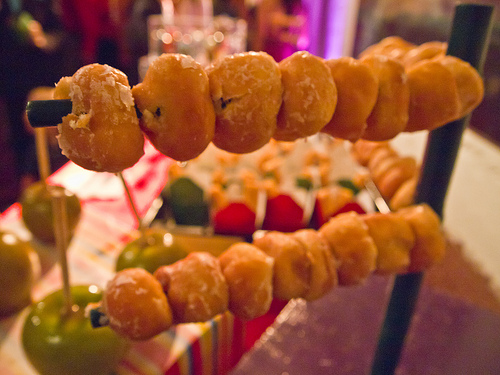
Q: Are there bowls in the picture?
A: No, there are no bowls.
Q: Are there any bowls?
A: No, there are no bowls.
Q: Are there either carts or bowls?
A: No, there are no bowls or carts.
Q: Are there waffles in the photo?
A: No, there are no waffles.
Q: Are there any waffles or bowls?
A: No, there are no waffles or bowls.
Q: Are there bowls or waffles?
A: No, there are no waffles or bowls.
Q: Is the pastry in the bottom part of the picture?
A: Yes, the pastry is in the bottom of the image.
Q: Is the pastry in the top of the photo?
A: No, the pastry is in the bottom of the image.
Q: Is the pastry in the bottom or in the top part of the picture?
A: The pastry is in the bottom of the image.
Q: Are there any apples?
A: Yes, there is an apple.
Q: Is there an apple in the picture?
A: Yes, there is an apple.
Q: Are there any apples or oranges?
A: Yes, there is an apple.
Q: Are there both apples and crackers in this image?
A: No, there is an apple but no crackers.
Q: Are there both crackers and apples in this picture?
A: No, there is an apple but no crackers.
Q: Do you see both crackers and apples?
A: No, there is an apple but no crackers.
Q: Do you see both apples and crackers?
A: No, there is an apple but no crackers.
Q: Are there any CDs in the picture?
A: No, there are no cds.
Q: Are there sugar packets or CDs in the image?
A: No, there are no CDs or sugar packets.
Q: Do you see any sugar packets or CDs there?
A: No, there are no CDs or sugar packets.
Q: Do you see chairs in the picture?
A: No, there are no chairs.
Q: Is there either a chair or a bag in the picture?
A: No, there are no chairs or bags.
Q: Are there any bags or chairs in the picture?
A: No, there are no chairs or bags.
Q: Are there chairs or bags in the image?
A: No, there are no chairs or bags.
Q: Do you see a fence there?
A: No, there are no fences.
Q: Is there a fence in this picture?
A: No, there are no fences.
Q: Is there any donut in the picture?
A: Yes, there is a donut.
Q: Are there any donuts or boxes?
A: Yes, there is a donut.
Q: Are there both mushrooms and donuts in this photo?
A: No, there is a donut but no mushrooms.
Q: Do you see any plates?
A: No, there are no plates.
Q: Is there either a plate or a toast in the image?
A: No, there are no plates or toasts.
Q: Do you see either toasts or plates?
A: No, there are no plates or toasts.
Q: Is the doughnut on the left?
A: Yes, the doughnut is on the left of the image.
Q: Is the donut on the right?
A: No, the donut is on the left of the image.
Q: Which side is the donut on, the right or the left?
A: The donut is on the left of the image.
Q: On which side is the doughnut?
A: The doughnut is on the left of the image.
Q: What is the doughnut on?
A: The doughnut is on the pole.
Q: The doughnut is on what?
A: The doughnut is on the pole.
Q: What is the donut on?
A: The doughnut is on the pole.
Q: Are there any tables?
A: Yes, there is a table.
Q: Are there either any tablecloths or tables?
A: Yes, there is a table.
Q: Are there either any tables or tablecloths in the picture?
A: Yes, there is a table.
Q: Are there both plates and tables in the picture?
A: No, there is a table but no plates.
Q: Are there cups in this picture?
A: No, there are no cups.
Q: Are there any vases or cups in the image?
A: No, there are no cups or vases.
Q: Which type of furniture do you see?
A: The furniture is a table.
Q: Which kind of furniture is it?
A: The piece of furniture is a table.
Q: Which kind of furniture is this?
A: This is a table.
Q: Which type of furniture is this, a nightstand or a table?
A: This is a table.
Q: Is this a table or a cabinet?
A: This is a table.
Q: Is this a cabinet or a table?
A: This is a table.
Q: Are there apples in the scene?
A: Yes, there is an apple.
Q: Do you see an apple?
A: Yes, there is an apple.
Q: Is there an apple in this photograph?
A: Yes, there is an apple.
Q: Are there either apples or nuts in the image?
A: Yes, there is an apple.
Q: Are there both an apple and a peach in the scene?
A: No, there is an apple but no peaches.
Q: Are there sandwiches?
A: No, there are no sandwiches.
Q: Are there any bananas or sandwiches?
A: No, there are no sandwiches or bananas.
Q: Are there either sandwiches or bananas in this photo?
A: No, there are no sandwiches or bananas.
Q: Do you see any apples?
A: Yes, there is an apple.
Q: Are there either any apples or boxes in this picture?
A: Yes, there is an apple.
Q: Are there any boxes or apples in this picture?
A: Yes, there is an apple.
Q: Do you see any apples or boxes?
A: Yes, there is an apple.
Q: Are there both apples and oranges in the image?
A: No, there is an apple but no oranges.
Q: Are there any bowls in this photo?
A: No, there are no bowls.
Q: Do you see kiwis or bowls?
A: No, there are no bowls or kiwis.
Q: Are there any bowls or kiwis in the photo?
A: No, there are no bowls or kiwis.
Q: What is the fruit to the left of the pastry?
A: The fruit is an apple.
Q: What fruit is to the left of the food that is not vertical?
A: The fruit is an apple.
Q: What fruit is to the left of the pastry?
A: The fruit is an apple.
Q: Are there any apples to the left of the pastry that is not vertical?
A: Yes, there is an apple to the left of the pastry.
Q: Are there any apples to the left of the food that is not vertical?
A: Yes, there is an apple to the left of the pastry.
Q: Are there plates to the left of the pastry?
A: No, there is an apple to the left of the pastry.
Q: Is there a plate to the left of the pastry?
A: No, there is an apple to the left of the pastry.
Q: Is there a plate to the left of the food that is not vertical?
A: No, there is an apple to the left of the pastry.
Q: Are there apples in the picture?
A: Yes, there is an apple.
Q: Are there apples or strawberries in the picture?
A: Yes, there is an apple.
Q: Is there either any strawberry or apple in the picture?
A: Yes, there is an apple.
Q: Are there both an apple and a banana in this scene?
A: No, there is an apple but no bananas.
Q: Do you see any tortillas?
A: No, there are no tortillas.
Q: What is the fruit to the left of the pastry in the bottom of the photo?
A: The fruit is an apple.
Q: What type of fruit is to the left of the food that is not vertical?
A: The fruit is an apple.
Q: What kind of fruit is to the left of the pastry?
A: The fruit is an apple.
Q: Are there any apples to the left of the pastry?
A: Yes, there is an apple to the left of the pastry.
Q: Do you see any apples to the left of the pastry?
A: Yes, there is an apple to the left of the pastry.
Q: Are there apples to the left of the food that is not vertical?
A: Yes, there is an apple to the left of the pastry.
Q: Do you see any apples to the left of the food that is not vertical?
A: Yes, there is an apple to the left of the pastry.